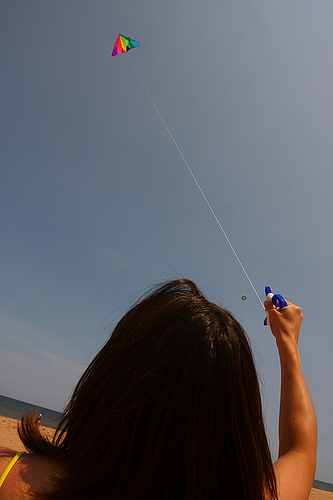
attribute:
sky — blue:
[15, 93, 186, 263]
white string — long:
[128, 54, 270, 314]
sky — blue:
[195, 38, 302, 126]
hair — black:
[16, 279, 278, 499]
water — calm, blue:
[16, 395, 62, 432]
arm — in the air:
[263, 290, 314, 498]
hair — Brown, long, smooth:
[38, 270, 255, 488]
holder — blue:
[263, 285, 281, 321]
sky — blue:
[3, 4, 325, 266]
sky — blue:
[1, 1, 332, 485]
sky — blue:
[56, 188, 136, 275]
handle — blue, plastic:
[262, 288, 283, 327]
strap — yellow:
[0, 438, 21, 487]